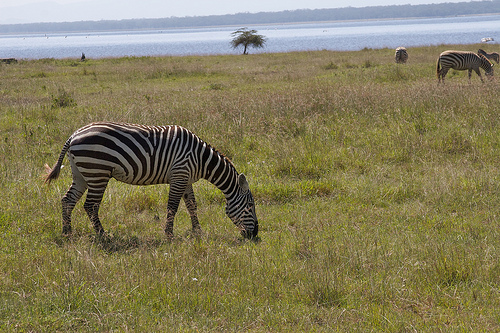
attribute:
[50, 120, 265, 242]
zebra — grazing, black, white, striped, wild, feeding, eating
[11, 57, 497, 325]
field — vast, grassy, hilly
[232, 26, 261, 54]
tree — single, loney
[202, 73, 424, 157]
grass — green, abundant, plenty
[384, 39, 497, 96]
zebras — grazing, feeding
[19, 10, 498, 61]
ocean — background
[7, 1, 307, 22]
sky — blue, hazy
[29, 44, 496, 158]
herd — grazing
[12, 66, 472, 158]
plain — open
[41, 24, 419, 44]
water — large, blue, background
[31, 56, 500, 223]
meadow — grass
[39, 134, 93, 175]
tail — waving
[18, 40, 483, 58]
beach — sandy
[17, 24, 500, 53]
river — flowing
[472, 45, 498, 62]
zebra — young, baby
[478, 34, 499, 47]
traps — floating